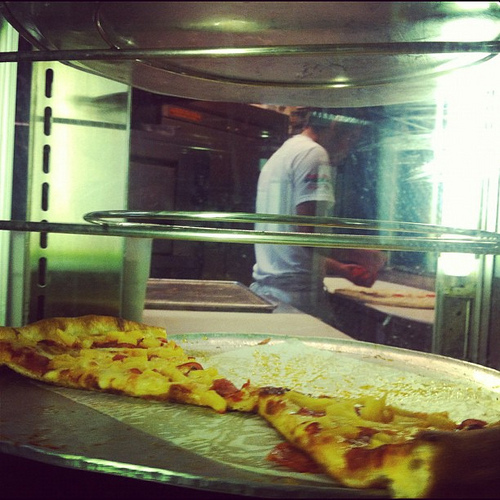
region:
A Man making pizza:
[249, 105, 446, 324]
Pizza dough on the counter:
[333, 284, 439, 309]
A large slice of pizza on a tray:
[0, 312, 257, 411]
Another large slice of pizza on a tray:
[258, 383, 499, 498]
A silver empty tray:
[138, 276, 274, 311]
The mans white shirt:
[246, 135, 338, 282]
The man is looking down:
[306, 105, 371, 166]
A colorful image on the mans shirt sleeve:
[302, 168, 334, 200]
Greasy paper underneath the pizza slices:
[139, 408, 261, 443]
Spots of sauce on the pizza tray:
[18, 418, 108, 453]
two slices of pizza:
[0, 300, 496, 497]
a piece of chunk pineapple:
[50, 322, 78, 347]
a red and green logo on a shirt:
[299, 162, 333, 198]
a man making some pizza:
[247, 85, 390, 335]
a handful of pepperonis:
[347, 255, 384, 287]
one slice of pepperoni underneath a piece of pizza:
[266, 434, 326, 480]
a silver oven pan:
[135, 270, 285, 319]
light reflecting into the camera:
[387, 1, 498, 280]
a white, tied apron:
[242, 260, 344, 330]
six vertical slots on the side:
[33, 63, 58, 293]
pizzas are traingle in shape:
[23, 320, 495, 490]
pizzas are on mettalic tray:
[30, 302, 487, 489]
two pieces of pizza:
[42, 320, 498, 491]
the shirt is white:
[257, 140, 352, 286]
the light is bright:
[386, 128, 498, 211]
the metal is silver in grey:
[68, 206, 498, 259]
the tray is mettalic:
[163, 266, 268, 312]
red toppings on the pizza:
[347, 257, 434, 298]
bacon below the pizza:
[256, 435, 308, 473]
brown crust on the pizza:
[415, 436, 492, 495]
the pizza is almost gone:
[2, 317, 498, 497]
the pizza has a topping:
[0, 315, 497, 495]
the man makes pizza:
[251, 105, 441, 299]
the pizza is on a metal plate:
[14, 333, 496, 495]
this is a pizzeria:
[0, 1, 497, 496]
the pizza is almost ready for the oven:
[337, 287, 436, 307]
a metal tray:
[141, 278, 274, 311]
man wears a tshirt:
[257, 133, 329, 288]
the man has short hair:
[308, 106, 363, 133]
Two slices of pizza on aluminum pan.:
[7, 308, 498, 498]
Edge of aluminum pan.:
[7, 397, 302, 496]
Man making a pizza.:
[248, 93, 445, 319]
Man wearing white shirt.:
[242, 133, 348, 313]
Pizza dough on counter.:
[332, 278, 450, 316]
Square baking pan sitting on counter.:
[150, 266, 290, 318]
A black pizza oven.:
[133, 128, 226, 278]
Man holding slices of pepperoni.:
[338, 256, 381, 292]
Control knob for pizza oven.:
[182, 181, 211, 212]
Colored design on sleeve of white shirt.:
[298, 167, 335, 194]